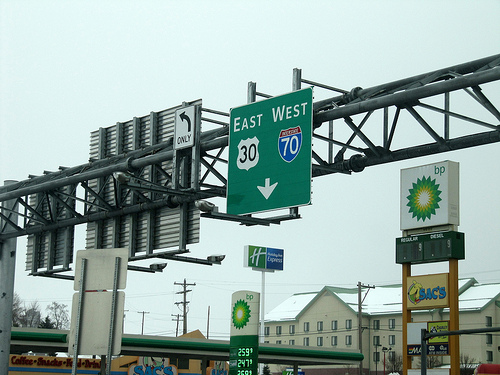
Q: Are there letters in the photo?
A: Yes, there are letters.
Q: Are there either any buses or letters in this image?
A: Yes, there are letters.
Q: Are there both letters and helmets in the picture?
A: No, there are letters but no helmets.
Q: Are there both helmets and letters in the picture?
A: No, there are letters but no helmets.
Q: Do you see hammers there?
A: No, there are no hammers.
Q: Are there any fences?
A: No, there are no fences.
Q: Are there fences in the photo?
A: No, there are no fences.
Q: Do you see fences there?
A: No, there are no fences.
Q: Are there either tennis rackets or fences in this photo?
A: No, there are no fences or tennis rackets.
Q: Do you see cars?
A: No, there are no cars.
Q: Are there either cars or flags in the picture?
A: No, there are no cars or flags.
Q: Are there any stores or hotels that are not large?
A: No, there is a hotel but it is large.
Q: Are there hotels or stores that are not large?
A: No, there is a hotel but it is large.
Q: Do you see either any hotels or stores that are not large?
A: No, there is a hotel but it is large.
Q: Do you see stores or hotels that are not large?
A: No, there is a hotel but it is large.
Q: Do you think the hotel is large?
A: Yes, the hotel is large.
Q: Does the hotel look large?
A: Yes, the hotel is large.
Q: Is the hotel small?
A: No, the hotel is large.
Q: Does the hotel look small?
A: No, the hotel is large.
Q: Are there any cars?
A: No, there are no cars.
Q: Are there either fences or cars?
A: No, there are no cars or fences.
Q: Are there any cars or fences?
A: No, there are no cars or fences.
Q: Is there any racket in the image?
A: No, there are no rackets.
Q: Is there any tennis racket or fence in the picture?
A: No, there are no rackets or fences.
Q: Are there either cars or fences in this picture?
A: No, there are no cars or fences.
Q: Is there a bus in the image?
A: No, there are no buses.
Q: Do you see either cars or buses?
A: No, there are no buses or cars.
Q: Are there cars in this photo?
A: No, there are no cars.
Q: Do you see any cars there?
A: No, there are no cars.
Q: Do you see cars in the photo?
A: No, there are no cars.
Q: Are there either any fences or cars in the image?
A: No, there are no cars or fences.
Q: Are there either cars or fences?
A: No, there are no cars or fences.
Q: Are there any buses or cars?
A: No, there are no cars or buses.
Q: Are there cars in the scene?
A: No, there are no cars.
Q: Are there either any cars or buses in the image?
A: No, there are no cars or buses.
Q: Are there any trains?
A: No, there are no trains.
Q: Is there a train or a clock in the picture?
A: No, there are no trains or clocks.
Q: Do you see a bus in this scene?
A: No, there are no buses.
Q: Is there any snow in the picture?
A: Yes, there is snow.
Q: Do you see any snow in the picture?
A: Yes, there is snow.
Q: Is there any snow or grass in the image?
A: Yes, there is snow.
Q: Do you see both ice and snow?
A: No, there is snow but no ice.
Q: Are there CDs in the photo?
A: No, there are no cds.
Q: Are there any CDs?
A: No, there are no cds.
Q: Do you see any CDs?
A: No, there are no cds.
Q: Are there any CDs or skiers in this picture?
A: No, there are no CDs or skiers.